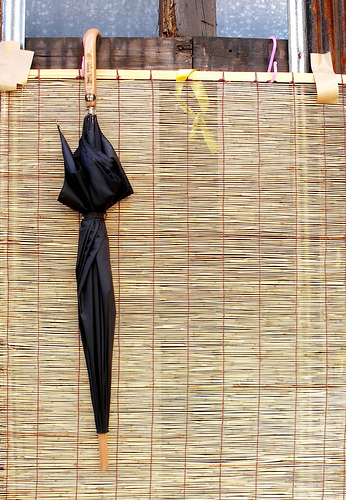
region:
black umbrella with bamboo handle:
[54, 27, 127, 471]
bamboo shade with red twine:
[1, 65, 343, 498]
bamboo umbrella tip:
[96, 431, 111, 471]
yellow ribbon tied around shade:
[173, 66, 218, 154]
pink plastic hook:
[263, 33, 278, 85]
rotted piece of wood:
[158, 1, 177, 39]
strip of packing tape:
[308, 49, 340, 107]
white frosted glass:
[25, 0, 287, 36]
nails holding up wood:
[182, 40, 213, 64]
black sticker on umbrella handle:
[83, 93, 95, 103]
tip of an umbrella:
[105, 450, 119, 460]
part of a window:
[227, 398, 236, 432]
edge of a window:
[178, 400, 194, 435]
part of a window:
[211, 388, 218, 398]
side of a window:
[214, 398, 222, 406]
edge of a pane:
[200, 353, 209, 369]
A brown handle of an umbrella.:
[83, 29, 101, 107]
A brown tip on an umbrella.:
[97, 432, 108, 471]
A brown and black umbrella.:
[56, 25, 134, 471]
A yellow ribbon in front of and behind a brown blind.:
[176, 67, 219, 154]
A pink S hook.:
[267, 35, 277, 83]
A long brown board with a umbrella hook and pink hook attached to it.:
[23, 33, 289, 73]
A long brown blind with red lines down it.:
[0, 63, 345, 496]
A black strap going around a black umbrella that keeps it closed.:
[79, 210, 105, 221]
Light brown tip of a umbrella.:
[95, 431, 109, 471]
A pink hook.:
[266, 36, 278, 84]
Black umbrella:
[33, 34, 188, 474]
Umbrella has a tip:
[88, 428, 130, 474]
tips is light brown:
[85, 433, 120, 478]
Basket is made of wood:
[146, 162, 314, 499]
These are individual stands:
[141, 312, 338, 493]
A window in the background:
[1, 2, 345, 79]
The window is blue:
[9, 4, 312, 41]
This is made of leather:
[44, 111, 156, 437]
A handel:
[289, 46, 345, 107]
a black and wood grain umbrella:
[55, 27, 135, 471]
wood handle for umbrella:
[82, 25, 101, 101]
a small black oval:
[83, 93, 95, 102]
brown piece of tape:
[310, 50, 338, 106]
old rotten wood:
[23, 34, 287, 72]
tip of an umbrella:
[96, 431, 108, 472]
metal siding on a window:
[2, 0, 24, 51]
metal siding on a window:
[286, 2, 307, 72]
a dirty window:
[25, 1, 290, 38]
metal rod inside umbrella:
[85, 106, 93, 113]